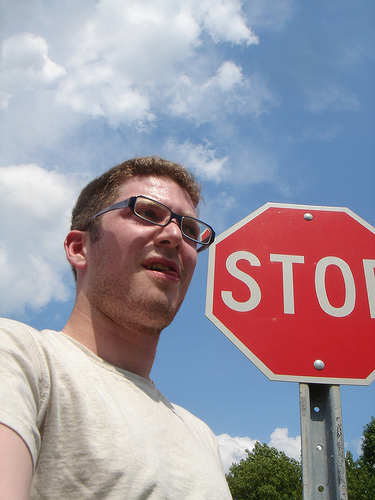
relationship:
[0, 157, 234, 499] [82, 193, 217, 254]
man wearing glasses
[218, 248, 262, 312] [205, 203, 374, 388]
letter on sign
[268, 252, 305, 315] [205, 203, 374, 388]
letter on sign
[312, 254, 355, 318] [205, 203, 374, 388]
letter on sign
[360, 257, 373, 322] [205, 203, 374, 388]
letter on sign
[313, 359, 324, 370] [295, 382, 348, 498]
bolt on pole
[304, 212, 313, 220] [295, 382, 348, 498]
bolts on pole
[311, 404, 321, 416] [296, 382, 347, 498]
hole on metal pole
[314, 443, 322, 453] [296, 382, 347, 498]
hole in metal pole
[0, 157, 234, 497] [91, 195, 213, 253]
man wearing eye glasses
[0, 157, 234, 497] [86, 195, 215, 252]
man wearing eye glasses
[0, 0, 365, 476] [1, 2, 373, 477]
cloud in sky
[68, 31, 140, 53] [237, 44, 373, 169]
cloud in sky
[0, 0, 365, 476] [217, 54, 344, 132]
cloud in sky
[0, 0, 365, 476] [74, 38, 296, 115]
cloud in sky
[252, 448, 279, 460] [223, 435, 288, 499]
leaves on trees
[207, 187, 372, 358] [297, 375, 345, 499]
sign on pole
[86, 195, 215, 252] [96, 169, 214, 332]
eye glasses on face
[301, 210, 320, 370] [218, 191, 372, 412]
bolts on sign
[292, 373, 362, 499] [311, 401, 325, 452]
pole with holes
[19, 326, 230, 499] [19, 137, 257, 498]
shirt on man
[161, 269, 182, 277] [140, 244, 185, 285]
tongue of mouth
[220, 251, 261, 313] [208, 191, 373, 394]
letter on sign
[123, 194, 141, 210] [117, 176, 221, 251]
frame on glasses